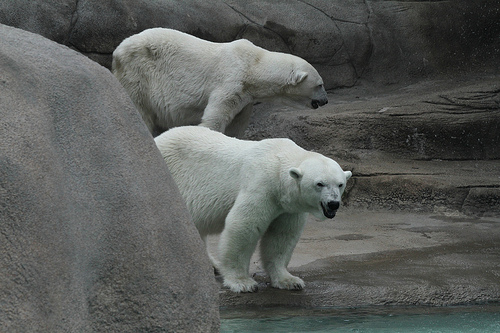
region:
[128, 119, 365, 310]
bear facing towards camera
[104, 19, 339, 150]
white bear facing right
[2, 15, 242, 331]
large gray gunite boulder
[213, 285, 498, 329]
pond of water in foreground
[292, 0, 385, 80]
crack in gray boulder in background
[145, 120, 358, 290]
large white polar bear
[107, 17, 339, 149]
white polar bear in background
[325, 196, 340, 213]
black polar bear nose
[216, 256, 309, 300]
two front bear paws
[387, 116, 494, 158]
white spots on gray rock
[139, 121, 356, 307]
white polar bear in foreground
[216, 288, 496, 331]
small water pond in foreground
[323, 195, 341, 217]
big black bear nose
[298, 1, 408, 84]
cracks in gray boulder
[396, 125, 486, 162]
white spots in gray boulder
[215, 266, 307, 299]
large polar bear paws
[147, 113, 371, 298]
polar bear looking at camera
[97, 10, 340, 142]
large bear facing right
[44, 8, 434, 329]
polar bear standing on rocks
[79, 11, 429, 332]
two polar bears standing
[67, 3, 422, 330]
polar bears standing outside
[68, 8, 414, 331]
two polar bears standing on rocks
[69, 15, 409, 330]
two white polar bears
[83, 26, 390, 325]
white polar bears standing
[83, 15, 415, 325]
white polar bears standing up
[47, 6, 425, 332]
white polar bears standing on rocks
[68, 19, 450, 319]
polars bears in a rocky area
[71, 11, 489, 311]
an area with polar bears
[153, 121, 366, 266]
White polar bear near water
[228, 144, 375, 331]
White polar bear near water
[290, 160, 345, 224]
White bear with a mean face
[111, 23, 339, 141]
Bear walking forward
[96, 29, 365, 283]
Two bears in a pen together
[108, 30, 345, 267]
White polar bears near water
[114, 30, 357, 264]
Two bears near rocks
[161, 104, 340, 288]
Rock in front of a bear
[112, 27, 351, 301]
two white big bears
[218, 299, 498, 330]
cold and clear water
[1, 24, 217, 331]
a big solid rock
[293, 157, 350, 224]
the bear with the open mouth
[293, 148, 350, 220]
the head of the white bear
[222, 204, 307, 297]
the two frontal bear legs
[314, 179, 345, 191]
two small eyes of the bear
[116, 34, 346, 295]
two bears in different positions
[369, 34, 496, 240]
ladder-shaped rocks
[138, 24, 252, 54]
back of the bear